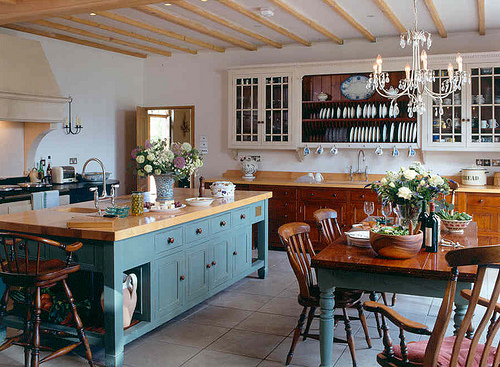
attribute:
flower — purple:
[173, 155, 189, 171]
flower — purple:
[170, 141, 184, 157]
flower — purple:
[143, 139, 157, 151]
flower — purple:
[129, 145, 144, 161]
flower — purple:
[185, 146, 195, 162]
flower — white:
[180, 140, 195, 155]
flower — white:
[154, 168, 165, 175]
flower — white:
[145, 152, 159, 163]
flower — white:
[134, 153, 146, 165]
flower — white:
[141, 162, 156, 176]